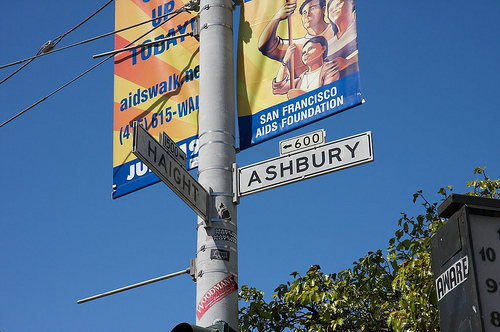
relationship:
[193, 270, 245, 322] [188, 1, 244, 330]
sticher on pole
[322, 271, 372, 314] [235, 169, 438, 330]
leaves on tree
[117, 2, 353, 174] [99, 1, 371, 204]
aids walk on sign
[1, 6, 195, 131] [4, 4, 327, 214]
cables in air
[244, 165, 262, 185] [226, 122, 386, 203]
letter on sign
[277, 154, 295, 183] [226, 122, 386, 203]
h on sign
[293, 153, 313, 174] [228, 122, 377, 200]
b on sign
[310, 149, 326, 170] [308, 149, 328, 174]
u on sign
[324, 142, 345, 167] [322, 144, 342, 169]
r on sign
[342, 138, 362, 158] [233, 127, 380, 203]
y on sign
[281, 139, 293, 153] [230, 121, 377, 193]
arrow on sign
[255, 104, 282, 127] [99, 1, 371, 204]
san on sign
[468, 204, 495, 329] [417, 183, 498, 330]
clock has corner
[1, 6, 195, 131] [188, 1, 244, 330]
cables on pole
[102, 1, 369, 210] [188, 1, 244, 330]
banner on pole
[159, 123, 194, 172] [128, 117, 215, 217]
numbers on top of sign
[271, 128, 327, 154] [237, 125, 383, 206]
numbers on top of sign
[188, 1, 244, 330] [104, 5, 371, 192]
pole holding signs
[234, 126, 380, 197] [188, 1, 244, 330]
signs holding pole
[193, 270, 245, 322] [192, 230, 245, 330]
sticher on sign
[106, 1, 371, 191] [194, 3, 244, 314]
flag on pole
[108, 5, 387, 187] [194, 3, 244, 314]
flag on pole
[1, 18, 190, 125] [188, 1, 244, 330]
lines connecting pole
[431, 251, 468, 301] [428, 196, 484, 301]
sticker on box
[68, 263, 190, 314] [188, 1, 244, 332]
pole sticking pole